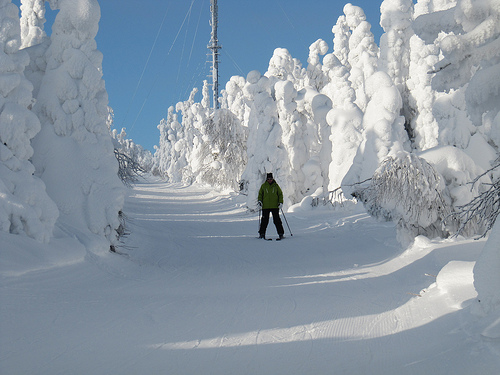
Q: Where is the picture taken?
A: A mountain.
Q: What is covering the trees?
A: Snow.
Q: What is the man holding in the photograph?
A: Ski poles.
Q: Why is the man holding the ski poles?
A: To ski.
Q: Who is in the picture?
A: A man.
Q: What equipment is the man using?
A: Skis.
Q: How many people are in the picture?
A: One.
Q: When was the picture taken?
A: Daytime.